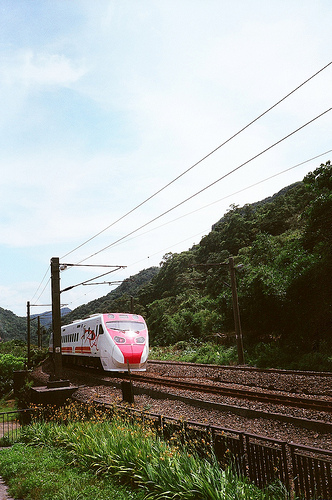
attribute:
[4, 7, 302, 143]
sky — pale, blue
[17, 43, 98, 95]
clouds — fluffy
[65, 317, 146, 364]
train — White 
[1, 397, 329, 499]
fence — brown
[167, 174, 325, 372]
hill — large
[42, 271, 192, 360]
hill — large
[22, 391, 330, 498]
plants — hight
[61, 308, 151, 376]
train — approaching, passenger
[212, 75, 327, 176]
rail — marbled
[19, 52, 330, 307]
electrical wire — long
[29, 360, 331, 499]
gravel — brown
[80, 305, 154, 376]
tracks — red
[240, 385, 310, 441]
track — rocky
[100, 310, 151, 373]
front — red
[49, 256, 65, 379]
pole — wood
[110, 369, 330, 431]
tracks — brown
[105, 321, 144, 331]
window — CONDUCTORS 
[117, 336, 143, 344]
lights — red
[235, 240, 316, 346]
tree — green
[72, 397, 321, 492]
fence — black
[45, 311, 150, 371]
train — white